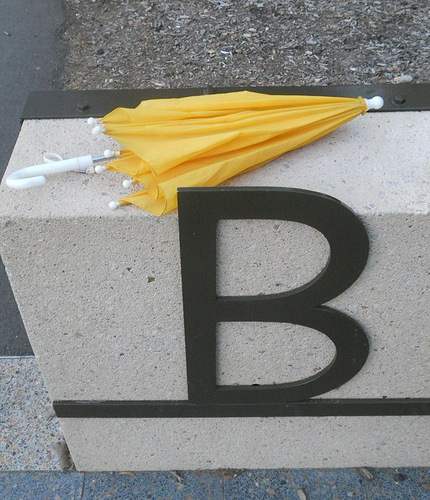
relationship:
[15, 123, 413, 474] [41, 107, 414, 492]
wall side of building